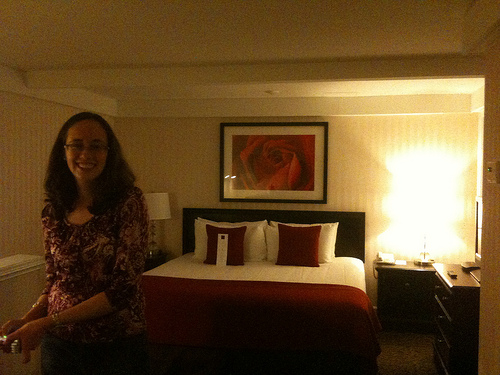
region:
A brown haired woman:
[0, 111, 151, 373]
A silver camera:
[1, 332, 20, 354]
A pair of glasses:
[58, 141, 112, 155]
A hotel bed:
[140, 205, 374, 373]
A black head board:
[183, 207, 364, 262]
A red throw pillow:
[275, 222, 322, 269]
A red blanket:
[140, 272, 382, 363]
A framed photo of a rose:
[217, 119, 327, 204]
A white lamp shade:
[143, 189, 173, 219]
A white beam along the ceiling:
[20, 56, 489, 89]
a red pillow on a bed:
[276, 223, 322, 268]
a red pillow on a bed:
[200, 222, 249, 267]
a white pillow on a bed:
[190, 218, 267, 262]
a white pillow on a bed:
[263, 220, 339, 262]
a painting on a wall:
[216, 120, 328, 205]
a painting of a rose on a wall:
[217, 120, 330, 204]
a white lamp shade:
[135, 191, 170, 254]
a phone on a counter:
[370, 251, 396, 277]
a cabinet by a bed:
[370, 255, 438, 332]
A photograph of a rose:
[215, 117, 330, 207]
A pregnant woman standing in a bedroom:
[36, 110, 148, 373]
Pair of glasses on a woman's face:
[61, 137, 105, 154]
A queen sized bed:
[125, 200, 373, 371]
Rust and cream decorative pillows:
[186, 214, 338, 267]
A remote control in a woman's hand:
[0, 328, 17, 347]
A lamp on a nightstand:
[138, 188, 175, 255]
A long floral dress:
[36, 203, 138, 368]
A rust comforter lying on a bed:
[102, 257, 366, 371]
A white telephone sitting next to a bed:
[374, 250, 396, 265]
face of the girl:
[46, 108, 135, 208]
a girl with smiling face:
[48, 117, 135, 193]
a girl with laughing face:
[41, 105, 135, 210]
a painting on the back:
[206, 102, 350, 200]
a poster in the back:
[204, 103, 379, 226]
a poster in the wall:
[197, 105, 364, 222]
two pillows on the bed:
[177, 215, 365, 265]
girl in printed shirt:
[16, 98, 204, 364]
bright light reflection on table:
[390, 152, 452, 275]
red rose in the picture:
[236, 146, 314, 188]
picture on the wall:
[218, 123, 340, 208]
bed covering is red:
[155, 287, 370, 354]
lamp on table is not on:
[144, 185, 164, 251]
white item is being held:
[0, 325, 27, 355]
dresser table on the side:
[424, 264, 476, 374]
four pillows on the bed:
[198, 216, 334, 273]